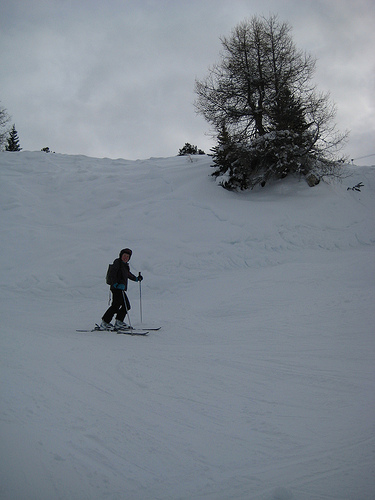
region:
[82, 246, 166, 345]
a child skiier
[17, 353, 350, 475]
freshly packed powdered snow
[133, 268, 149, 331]
a ski pole for walking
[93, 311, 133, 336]
white skiing boots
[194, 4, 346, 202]
dead tree in the snow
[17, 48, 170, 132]
gray and white sky above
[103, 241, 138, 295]
boy with a jacket and hat on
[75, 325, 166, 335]
the boy's skiing equipment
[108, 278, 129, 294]
blue glove on the boy's hand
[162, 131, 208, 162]
snow capped tree in the distance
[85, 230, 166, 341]
a person in black on skis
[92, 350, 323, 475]
snow filled with ski tracks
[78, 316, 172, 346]
black skis on a person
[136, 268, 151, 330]
a black ski pole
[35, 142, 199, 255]
a hillside covered in snow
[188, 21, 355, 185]
a large leafless tree on a slope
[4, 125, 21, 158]
a pine tree on the hill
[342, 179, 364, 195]
a plant in the snow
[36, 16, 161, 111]
a grey cloudy sky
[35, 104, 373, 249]
a large snowy hillside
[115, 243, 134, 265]
the head of a person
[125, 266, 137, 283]
the arm of a person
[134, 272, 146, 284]
the hand of a person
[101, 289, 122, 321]
the leg of a person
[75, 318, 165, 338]
a pair of skis on the snow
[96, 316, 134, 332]
a pair of white ski boots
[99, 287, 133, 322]
a pair of black pants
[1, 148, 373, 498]
white snow on the ground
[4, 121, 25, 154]
a green tree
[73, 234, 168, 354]
person riding some skis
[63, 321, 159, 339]
ski covered in snow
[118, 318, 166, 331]
ski covered in snow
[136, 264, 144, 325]
long metal ski pole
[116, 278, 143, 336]
long metal ski pole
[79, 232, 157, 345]
person wearing a hat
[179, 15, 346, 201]
tree with no leaves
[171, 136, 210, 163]
tip of a tree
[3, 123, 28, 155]
top of a tree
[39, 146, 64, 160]
top of a tree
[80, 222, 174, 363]
a boy skiing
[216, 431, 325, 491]
ski tracks in the snow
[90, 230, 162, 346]
a boy wearing a black parka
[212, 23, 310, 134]
a brown bare tree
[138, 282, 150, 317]
a metal ski pole in his hand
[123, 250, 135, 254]
a black hat covering a head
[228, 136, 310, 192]
a bush laden with white snow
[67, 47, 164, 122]
thick gray clouds in the sky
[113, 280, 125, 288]
a hand covered by a blue glove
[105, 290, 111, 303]
a black cord dangling down